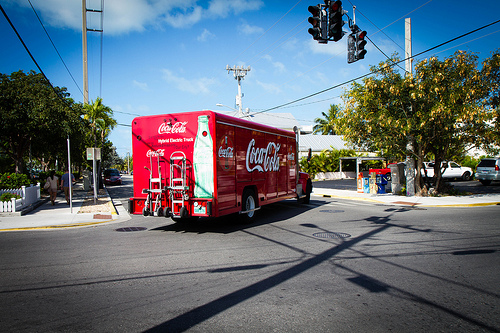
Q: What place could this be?
A: It is a street.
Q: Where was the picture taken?
A: It was taken at the street.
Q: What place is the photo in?
A: It is at the street.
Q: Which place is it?
A: It is a street.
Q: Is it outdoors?
A: Yes, it is outdoors.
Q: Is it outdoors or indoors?
A: It is outdoors.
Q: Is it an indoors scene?
A: No, it is outdoors.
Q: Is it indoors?
A: No, it is outdoors.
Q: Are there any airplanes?
A: No, there are no airplanes.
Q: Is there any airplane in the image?
A: No, there are no airplanes.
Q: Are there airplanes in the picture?
A: No, there are no airplanes.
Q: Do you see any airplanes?
A: No, there are no airplanes.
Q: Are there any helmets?
A: No, there are no helmets.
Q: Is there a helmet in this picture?
A: No, there are no helmets.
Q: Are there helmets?
A: No, there are no helmets.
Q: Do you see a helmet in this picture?
A: No, there are no helmets.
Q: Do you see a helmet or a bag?
A: No, there are no helmets or bags.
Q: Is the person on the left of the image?
A: Yes, the person is on the left of the image.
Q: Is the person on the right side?
A: No, the person is on the left of the image.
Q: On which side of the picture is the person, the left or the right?
A: The person is on the left of the image.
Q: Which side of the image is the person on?
A: The person is on the left of the image.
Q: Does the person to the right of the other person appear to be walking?
A: Yes, the person is walking.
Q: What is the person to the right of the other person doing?
A: The person is walking.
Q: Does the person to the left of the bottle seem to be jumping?
A: No, the person is walking.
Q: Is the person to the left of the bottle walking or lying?
A: The person is walking.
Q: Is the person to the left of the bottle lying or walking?
A: The person is walking.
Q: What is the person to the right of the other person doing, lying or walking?
A: The person is walking.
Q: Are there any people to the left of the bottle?
A: Yes, there is a person to the left of the bottle.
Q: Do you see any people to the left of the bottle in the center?
A: Yes, there is a person to the left of the bottle.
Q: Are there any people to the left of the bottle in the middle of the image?
A: Yes, there is a person to the left of the bottle.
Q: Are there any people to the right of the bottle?
A: No, the person is to the left of the bottle.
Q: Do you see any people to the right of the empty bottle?
A: No, the person is to the left of the bottle.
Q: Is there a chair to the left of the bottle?
A: No, there is a person to the left of the bottle.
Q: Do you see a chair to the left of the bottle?
A: No, there is a person to the left of the bottle.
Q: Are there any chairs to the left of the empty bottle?
A: No, there is a person to the left of the bottle.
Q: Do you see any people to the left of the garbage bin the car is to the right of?
A: Yes, there is a person to the left of the garbage can.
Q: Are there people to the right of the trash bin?
A: No, the person is to the left of the trash bin.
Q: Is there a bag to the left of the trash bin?
A: No, there is a person to the left of the trash bin.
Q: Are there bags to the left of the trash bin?
A: No, there is a person to the left of the trash bin.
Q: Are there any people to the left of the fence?
A: No, the person is to the right of the fence.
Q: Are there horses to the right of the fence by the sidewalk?
A: No, there is a person to the right of the fence.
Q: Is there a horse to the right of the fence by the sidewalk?
A: No, there is a person to the right of the fence.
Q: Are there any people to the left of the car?
A: Yes, there is a person to the left of the car.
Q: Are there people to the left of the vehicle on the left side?
A: Yes, there is a person to the left of the car.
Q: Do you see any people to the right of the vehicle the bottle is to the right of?
A: No, the person is to the left of the car.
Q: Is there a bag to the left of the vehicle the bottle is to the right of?
A: No, there is a person to the left of the car.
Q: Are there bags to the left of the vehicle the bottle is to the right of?
A: No, there is a person to the left of the car.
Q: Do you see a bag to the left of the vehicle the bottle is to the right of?
A: No, there is a person to the left of the car.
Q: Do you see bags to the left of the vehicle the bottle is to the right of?
A: No, there is a person to the left of the car.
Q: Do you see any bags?
A: No, there are no bags.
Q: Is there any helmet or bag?
A: No, there are no bags or helmets.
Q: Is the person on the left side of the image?
A: Yes, the person is on the left of the image.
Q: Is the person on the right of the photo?
A: No, the person is on the left of the image.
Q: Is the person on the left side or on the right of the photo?
A: The person is on the left of the image.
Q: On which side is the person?
A: The person is on the left of the image.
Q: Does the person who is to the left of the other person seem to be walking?
A: Yes, the person is walking.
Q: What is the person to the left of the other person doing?
A: The person is walking.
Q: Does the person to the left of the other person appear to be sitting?
A: No, the person is walking.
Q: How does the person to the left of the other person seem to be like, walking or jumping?
A: The person is walking.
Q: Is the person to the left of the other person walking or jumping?
A: The person is walking.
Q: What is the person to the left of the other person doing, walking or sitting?
A: The person is walking.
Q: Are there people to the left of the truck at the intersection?
A: Yes, there is a person to the left of the truck.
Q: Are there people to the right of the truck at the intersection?
A: No, the person is to the left of the truck.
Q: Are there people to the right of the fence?
A: Yes, there is a person to the right of the fence.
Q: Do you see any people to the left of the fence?
A: No, the person is to the right of the fence.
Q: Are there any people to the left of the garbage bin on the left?
A: Yes, there is a person to the left of the garbage can.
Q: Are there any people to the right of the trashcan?
A: No, the person is to the left of the trashcan.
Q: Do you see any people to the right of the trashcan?
A: No, the person is to the left of the trashcan.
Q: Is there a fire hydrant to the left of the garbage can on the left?
A: No, there is a person to the left of the trash can.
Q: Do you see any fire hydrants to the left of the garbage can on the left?
A: No, there is a person to the left of the trash can.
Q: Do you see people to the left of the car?
A: Yes, there is a person to the left of the car.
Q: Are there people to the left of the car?
A: Yes, there is a person to the left of the car.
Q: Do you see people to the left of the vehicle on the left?
A: Yes, there is a person to the left of the car.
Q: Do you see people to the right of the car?
A: No, the person is to the left of the car.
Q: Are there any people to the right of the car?
A: No, the person is to the left of the car.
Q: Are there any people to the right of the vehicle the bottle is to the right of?
A: No, the person is to the left of the car.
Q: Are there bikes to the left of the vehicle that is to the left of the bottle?
A: No, there is a person to the left of the car.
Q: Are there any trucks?
A: Yes, there is a truck.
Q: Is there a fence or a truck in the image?
A: Yes, there is a truck.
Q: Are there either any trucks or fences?
A: Yes, there is a truck.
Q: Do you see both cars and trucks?
A: Yes, there are both a truck and a car.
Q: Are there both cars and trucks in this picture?
A: Yes, there are both a truck and a car.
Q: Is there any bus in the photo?
A: No, there are no buses.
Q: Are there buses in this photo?
A: No, there are no buses.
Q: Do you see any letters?
A: Yes, there are letters.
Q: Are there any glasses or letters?
A: Yes, there are letters.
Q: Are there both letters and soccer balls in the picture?
A: No, there are letters but no soccer balls.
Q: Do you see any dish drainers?
A: No, there are no dish drainers.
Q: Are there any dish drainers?
A: No, there are no dish drainers.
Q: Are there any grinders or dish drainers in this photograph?
A: No, there are no dish drainers or grinders.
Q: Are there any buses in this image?
A: No, there are no buses.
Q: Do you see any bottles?
A: Yes, there is a bottle.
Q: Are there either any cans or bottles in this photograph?
A: Yes, there is a bottle.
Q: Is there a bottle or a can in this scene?
A: Yes, there is a bottle.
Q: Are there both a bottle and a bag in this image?
A: No, there is a bottle but no bags.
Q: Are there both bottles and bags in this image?
A: No, there is a bottle but no bags.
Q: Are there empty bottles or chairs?
A: Yes, there is an empty bottle.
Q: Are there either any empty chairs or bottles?
A: Yes, there is an empty bottle.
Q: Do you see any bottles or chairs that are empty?
A: Yes, the bottle is empty.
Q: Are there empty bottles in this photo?
A: Yes, there is an empty bottle.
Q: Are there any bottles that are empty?
A: Yes, there is a bottle that is empty.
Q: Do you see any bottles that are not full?
A: Yes, there is a empty bottle.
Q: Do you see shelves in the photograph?
A: No, there are no shelves.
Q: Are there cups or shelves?
A: No, there are no shelves or cups.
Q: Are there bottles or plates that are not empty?
A: No, there is a bottle but it is empty.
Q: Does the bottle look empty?
A: Yes, the bottle is empty.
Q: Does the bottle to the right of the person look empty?
A: Yes, the bottle is empty.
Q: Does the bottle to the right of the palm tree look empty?
A: Yes, the bottle is empty.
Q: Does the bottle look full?
A: No, the bottle is empty.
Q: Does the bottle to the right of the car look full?
A: No, the bottle is empty.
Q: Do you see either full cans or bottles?
A: No, there is a bottle but it is empty.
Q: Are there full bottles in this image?
A: No, there is a bottle but it is empty.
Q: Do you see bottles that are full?
A: No, there is a bottle but it is empty.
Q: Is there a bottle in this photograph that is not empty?
A: No, there is a bottle but it is empty.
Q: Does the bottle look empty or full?
A: The bottle is empty.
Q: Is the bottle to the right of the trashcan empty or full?
A: The bottle is empty.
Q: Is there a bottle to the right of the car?
A: Yes, there is a bottle to the right of the car.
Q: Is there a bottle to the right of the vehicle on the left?
A: Yes, there is a bottle to the right of the car.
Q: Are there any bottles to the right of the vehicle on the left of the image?
A: Yes, there is a bottle to the right of the car.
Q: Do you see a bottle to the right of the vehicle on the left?
A: Yes, there is a bottle to the right of the car.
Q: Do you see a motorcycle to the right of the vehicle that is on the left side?
A: No, there is a bottle to the right of the car.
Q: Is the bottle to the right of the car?
A: Yes, the bottle is to the right of the car.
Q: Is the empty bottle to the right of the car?
A: Yes, the bottle is to the right of the car.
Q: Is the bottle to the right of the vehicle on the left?
A: Yes, the bottle is to the right of the car.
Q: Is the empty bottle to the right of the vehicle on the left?
A: Yes, the bottle is to the right of the car.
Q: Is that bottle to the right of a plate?
A: No, the bottle is to the right of the car.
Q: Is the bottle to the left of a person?
A: No, the bottle is to the right of a person.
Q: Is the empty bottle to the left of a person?
A: No, the bottle is to the right of a person.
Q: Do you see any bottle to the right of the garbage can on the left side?
A: Yes, there is a bottle to the right of the trashcan.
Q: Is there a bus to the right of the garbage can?
A: No, there is a bottle to the right of the garbage can.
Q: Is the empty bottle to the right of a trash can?
A: Yes, the bottle is to the right of a trash can.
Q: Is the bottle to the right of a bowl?
A: No, the bottle is to the right of a trash can.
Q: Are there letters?
A: Yes, there are letters.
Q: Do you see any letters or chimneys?
A: Yes, there are letters.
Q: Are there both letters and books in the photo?
A: No, there are letters but no books.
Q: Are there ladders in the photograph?
A: No, there are no ladders.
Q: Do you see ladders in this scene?
A: No, there are no ladders.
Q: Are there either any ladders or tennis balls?
A: No, there are no ladders or tennis balls.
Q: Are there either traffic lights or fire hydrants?
A: Yes, there is a traffic light.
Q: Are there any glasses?
A: No, there are no glasses.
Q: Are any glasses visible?
A: No, there are no glasses.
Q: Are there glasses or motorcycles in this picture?
A: No, there are no glasses or motorcycles.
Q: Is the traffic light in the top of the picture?
A: Yes, the traffic light is in the top of the image.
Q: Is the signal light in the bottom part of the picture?
A: No, the signal light is in the top of the image.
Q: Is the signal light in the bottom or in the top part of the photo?
A: The signal light is in the top of the image.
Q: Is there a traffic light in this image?
A: Yes, there is a traffic light.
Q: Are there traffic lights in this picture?
A: Yes, there is a traffic light.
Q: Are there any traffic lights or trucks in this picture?
A: Yes, there is a traffic light.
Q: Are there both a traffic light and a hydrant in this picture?
A: No, there is a traffic light but no fire hydrants.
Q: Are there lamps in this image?
A: No, there are no lamps.